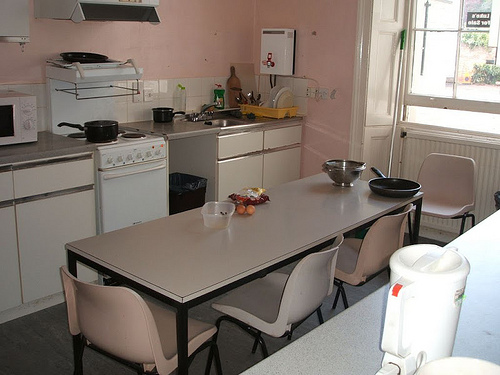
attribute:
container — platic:
[200, 196, 237, 228]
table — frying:
[61, 158, 424, 314]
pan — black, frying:
[366, 161, 421, 198]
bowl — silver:
[320, 155, 368, 187]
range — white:
[46, 56, 169, 287]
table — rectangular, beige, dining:
[60, 154, 424, 361]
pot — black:
[54, 115, 121, 148]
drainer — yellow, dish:
[238, 101, 300, 118]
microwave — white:
[5, 92, 42, 146]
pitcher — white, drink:
[379, 239, 471, 373]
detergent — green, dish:
[214, 96, 221, 106]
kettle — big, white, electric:
[375, 240, 470, 369]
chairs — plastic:
[55, 265, 216, 354]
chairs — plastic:
[215, 229, 346, 358]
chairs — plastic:
[335, 196, 418, 293]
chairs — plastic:
[408, 150, 479, 231]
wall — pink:
[255, 10, 485, 243]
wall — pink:
[9, 6, 256, 316]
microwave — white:
[6, 88, 39, 148]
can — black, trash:
[170, 167, 207, 214]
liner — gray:
[172, 171, 205, 205]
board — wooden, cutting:
[223, 61, 242, 107]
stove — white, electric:
[41, 59, 171, 259]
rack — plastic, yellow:
[237, 102, 300, 118]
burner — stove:
[81, 136, 118, 146]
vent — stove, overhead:
[32, 3, 161, 27]